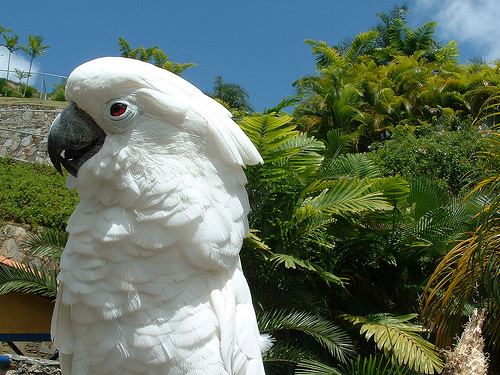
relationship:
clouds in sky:
[415, 5, 496, 52] [0, 3, 499, 57]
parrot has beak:
[45, 55, 264, 365] [48, 102, 105, 178]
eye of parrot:
[111, 105, 126, 120] [45, 55, 264, 365]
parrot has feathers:
[45, 55, 264, 365] [143, 102, 240, 258]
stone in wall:
[11, 140, 16, 151] [7, 107, 48, 164]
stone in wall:
[24, 136, 36, 149] [7, 107, 48, 164]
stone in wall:
[24, 148, 38, 158] [7, 107, 48, 164]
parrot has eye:
[45, 55, 264, 365] [111, 105, 126, 120]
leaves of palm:
[301, 177, 419, 216] [251, 116, 399, 306]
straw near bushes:
[439, 315, 487, 373] [273, 107, 499, 369]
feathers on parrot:
[143, 102, 240, 258] [45, 55, 264, 365]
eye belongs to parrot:
[111, 105, 126, 120] [45, 55, 264, 365]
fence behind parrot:
[5, 65, 68, 105] [45, 55, 264, 365]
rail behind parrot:
[5, 65, 63, 82] [45, 55, 264, 365]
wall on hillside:
[7, 107, 48, 164] [6, 92, 49, 269]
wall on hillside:
[2, 224, 56, 276] [6, 92, 49, 269]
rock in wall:
[4, 240, 21, 263] [2, 224, 56, 276]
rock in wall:
[2, 225, 27, 242] [2, 224, 56, 276]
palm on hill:
[4, 34, 16, 97] [6, 92, 49, 269]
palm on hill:
[23, 37, 49, 100] [6, 92, 49, 269]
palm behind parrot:
[251, 116, 399, 306] [45, 55, 264, 365]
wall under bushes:
[2, 224, 56, 276] [3, 229, 64, 297]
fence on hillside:
[5, 65, 68, 105] [6, 92, 49, 269]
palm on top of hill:
[4, 34, 16, 97] [6, 92, 49, 269]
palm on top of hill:
[251, 116, 399, 306] [6, 92, 49, 269]